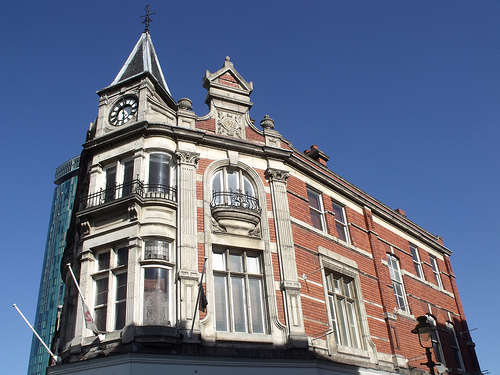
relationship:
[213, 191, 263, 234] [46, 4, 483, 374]
balcony on building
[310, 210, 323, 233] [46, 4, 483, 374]
window on building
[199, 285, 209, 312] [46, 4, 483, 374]
flag on building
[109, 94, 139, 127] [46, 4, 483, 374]
clock on building